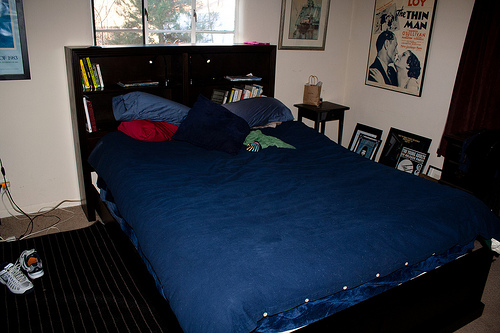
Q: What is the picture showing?
A: It is showing a bedroom.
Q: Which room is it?
A: It is a bedroom.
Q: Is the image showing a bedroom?
A: Yes, it is showing a bedroom.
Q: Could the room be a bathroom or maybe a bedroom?
A: It is a bedroom.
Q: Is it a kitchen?
A: No, it is a bedroom.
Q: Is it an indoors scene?
A: Yes, it is indoors.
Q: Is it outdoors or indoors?
A: It is indoors.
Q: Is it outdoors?
A: No, it is indoors.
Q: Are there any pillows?
A: Yes, there is a pillow.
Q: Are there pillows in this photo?
A: Yes, there is a pillow.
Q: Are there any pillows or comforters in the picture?
A: Yes, there is a pillow.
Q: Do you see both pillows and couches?
A: No, there is a pillow but no couches.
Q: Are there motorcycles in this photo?
A: No, there are no motorcycles.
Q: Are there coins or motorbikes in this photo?
A: No, there are no motorbikes or coins.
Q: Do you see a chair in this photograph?
A: No, there are no chairs.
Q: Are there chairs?
A: No, there are no chairs.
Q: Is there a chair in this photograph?
A: No, there are no chairs.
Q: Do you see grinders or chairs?
A: No, there are no chairs or grinders.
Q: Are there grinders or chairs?
A: No, there are no chairs or grinders.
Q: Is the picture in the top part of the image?
A: Yes, the picture is in the top of the image.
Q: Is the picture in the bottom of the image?
A: No, the picture is in the top of the image.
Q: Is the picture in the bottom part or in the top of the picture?
A: The picture is in the top of the image.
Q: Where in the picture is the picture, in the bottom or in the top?
A: The picture is in the top of the image.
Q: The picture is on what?
A: The picture is on the wall.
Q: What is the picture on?
A: The picture is on the wall.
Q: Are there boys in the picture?
A: No, there are no boys.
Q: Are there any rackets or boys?
A: No, there are no boys or rackets.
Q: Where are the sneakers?
A: The sneakers are on the floor.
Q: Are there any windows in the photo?
A: Yes, there is a window.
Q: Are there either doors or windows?
A: Yes, there is a window.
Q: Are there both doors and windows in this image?
A: No, there is a window but no doors.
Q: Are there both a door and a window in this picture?
A: No, there is a window but no doors.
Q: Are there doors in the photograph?
A: No, there are no doors.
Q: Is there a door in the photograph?
A: No, there are no doors.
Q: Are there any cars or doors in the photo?
A: No, there are no doors or cars.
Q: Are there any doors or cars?
A: No, there are no doors or cars.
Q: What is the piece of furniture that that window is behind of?
A: The piece of furniture is a bed.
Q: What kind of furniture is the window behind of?
A: The window is behind the bed.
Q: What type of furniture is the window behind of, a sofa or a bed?
A: The window is behind a bed.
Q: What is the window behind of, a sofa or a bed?
A: The window is behind a bed.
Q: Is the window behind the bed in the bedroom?
A: Yes, the window is behind the bed.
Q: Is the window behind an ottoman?
A: No, the window is behind the bed.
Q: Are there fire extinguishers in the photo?
A: No, there are no fire extinguishers.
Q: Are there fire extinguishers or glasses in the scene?
A: No, there are no fire extinguishers or glasses.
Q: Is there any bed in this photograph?
A: Yes, there is a bed.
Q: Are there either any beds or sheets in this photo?
A: Yes, there is a bed.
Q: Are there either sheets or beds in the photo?
A: Yes, there is a bed.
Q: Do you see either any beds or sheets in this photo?
A: Yes, there is a bed.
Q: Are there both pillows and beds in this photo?
A: Yes, there are both a bed and pillows.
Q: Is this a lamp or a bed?
A: This is a bed.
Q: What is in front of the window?
A: The bed is in front of the window.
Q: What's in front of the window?
A: The bed is in front of the window.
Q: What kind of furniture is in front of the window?
A: The piece of furniture is a bed.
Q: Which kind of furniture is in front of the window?
A: The piece of furniture is a bed.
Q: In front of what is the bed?
A: The bed is in front of the window.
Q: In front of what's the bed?
A: The bed is in front of the window.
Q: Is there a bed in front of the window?
A: Yes, there is a bed in front of the window.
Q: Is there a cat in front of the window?
A: No, there is a bed in front of the window.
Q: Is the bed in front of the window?
A: Yes, the bed is in front of the window.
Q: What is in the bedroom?
A: The bed is in the bedroom.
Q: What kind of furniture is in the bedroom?
A: The piece of furniture is a bed.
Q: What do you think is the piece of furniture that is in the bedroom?
A: The piece of furniture is a bed.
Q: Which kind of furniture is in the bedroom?
A: The piece of furniture is a bed.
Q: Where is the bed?
A: The bed is in the bedroom.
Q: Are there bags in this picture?
A: Yes, there is a bag.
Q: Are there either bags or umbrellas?
A: Yes, there is a bag.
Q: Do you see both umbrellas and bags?
A: No, there is a bag but no umbrellas.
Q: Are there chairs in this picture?
A: No, there are no chairs.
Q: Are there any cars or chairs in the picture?
A: No, there are no chairs or cars.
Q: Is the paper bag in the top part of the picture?
A: Yes, the bag is in the top of the image.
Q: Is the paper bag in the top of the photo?
A: Yes, the bag is in the top of the image.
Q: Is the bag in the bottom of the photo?
A: No, the bag is in the top of the image.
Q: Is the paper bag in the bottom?
A: No, the bag is in the top of the image.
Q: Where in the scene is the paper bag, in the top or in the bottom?
A: The bag is in the top of the image.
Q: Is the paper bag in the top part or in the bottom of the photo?
A: The bag is in the top of the image.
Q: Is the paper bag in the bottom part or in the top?
A: The bag is in the top of the image.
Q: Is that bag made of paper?
A: Yes, the bag is made of paper.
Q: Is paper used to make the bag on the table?
A: Yes, the bag is made of paper.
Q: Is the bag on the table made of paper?
A: Yes, the bag is made of paper.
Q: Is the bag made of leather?
A: No, the bag is made of paper.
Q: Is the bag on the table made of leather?
A: No, the bag is made of paper.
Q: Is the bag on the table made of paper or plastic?
A: The bag is made of paper.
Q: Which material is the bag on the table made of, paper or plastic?
A: The bag is made of paper.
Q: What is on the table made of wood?
A: The bag is on the table.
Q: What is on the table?
A: The bag is on the table.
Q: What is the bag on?
A: The bag is on the table.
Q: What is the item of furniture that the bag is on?
A: The piece of furniture is a table.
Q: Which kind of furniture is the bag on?
A: The bag is on the table.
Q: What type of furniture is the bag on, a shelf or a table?
A: The bag is on a table.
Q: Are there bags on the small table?
A: Yes, there is a bag on the table.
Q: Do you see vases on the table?
A: No, there is a bag on the table.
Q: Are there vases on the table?
A: No, there is a bag on the table.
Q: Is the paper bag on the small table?
A: Yes, the bag is on the table.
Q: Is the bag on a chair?
A: No, the bag is on the table.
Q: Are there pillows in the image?
A: Yes, there is a pillow.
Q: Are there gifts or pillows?
A: Yes, there is a pillow.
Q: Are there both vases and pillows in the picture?
A: No, there is a pillow but no vases.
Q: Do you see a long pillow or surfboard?
A: Yes, there is a long pillow.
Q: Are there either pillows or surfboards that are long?
A: Yes, the pillow is long.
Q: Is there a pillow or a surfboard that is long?
A: Yes, the pillow is long.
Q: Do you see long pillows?
A: Yes, there is a long pillow.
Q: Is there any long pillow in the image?
A: Yes, there is a long pillow.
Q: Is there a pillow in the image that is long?
A: Yes, there is a pillow that is long.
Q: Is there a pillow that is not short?
A: Yes, there is a long pillow.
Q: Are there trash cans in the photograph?
A: No, there are no trash cans.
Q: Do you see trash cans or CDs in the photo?
A: No, there are no trash cans or cds.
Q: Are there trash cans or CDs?
A: No, there are no trash cans or cds.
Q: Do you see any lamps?
A: No, there are no lamps.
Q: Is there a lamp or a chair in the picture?
A: No, there are no lamps or chairs.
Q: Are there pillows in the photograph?
A: Yes, there are pillows.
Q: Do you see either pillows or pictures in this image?
A: Yes, there are pillows.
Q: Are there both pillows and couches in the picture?
A: No, there are pillows but no couches.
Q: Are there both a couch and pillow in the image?
A: No, there are pillows but no couches.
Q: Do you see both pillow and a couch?
A: No, there are pillows but no couches.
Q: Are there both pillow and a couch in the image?
A: No, there are pillows but no couches.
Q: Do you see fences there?
A: No, there are no fences.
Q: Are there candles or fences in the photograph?
A: No, there are no fences or candles.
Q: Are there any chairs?
A: No, there are no chairs.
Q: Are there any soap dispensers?
A: No, there are no soap dispensers.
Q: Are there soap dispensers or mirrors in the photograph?
A: No, there are no soap dispensers or mirrors.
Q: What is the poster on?
A: The poster is on the wall.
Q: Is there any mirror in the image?
A: No, there are no mirrors.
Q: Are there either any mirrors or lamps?
A: No, there are no mirrors or lamps.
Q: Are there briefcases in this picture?
A: No, there are no briefcases.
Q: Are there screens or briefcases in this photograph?
A: No, there are no briefcases or screens.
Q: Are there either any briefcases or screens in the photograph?
A: No, there are no briefcases or screens.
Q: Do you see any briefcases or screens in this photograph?
A: No, there are no briefcases or screens.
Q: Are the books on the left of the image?
A: Yes, the books are on the left of the image.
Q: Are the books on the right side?
A: No, the books are on the left of the image.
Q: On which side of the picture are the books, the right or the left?
A: The books are on the left of the image.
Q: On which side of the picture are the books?
A: The books are on the left of the image.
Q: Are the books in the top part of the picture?
A: Yes, the books are in the top of the image.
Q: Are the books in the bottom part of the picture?
A: No, the books are in the top of the image.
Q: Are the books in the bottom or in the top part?
A: The books are in the top of the image.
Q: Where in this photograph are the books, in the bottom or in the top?
A: The books are in the top of the image.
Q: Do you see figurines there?
A: No, there are no figurines.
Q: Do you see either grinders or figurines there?
A: No, there are no figurines or grinders.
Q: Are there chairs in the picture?
A: No, there are no chairs.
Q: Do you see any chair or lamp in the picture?
A: No, there are no chairs or lamps.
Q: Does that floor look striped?
A: Yes, the floor is striped.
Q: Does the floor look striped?
A: Yes, the floor is striped.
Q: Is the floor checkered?
A: No, the floor is striped.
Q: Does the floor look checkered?
A: No, the floor is striped.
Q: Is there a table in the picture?
A: Yes, there is a table.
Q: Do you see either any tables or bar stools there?
A: Yes, there is a table.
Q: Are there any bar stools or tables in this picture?
A: Yes, there is a table.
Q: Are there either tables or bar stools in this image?
A: Yes, there is a table.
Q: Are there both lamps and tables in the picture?
A: No, there is a table but no lamps.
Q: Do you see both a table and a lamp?
A: No, there is a table but no lamps.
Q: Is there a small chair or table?
A: Yes, there is a small table.